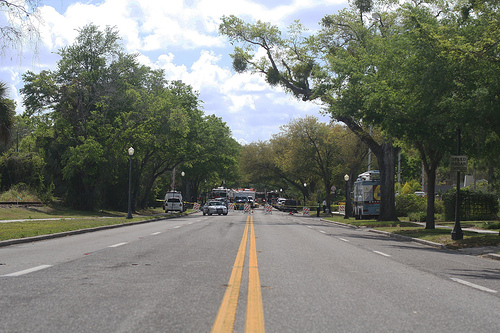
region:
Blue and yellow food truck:
[345, 167, 398, 217]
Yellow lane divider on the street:
[236, 207, 258, 329]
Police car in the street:
[195, 190, 230, 212]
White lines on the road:
[78, 212, 191, 257]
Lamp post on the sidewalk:
[121, 140, 140, 232]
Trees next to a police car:
[46, 72, 141, 201]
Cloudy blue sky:
[126, 19, 268, 111]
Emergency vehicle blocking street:
[218, 182, 287, 215]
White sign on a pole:
[452, 147, 471, 185]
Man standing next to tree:
[314, 197, 330, 214]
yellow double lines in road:
[213, 230, 269, 325]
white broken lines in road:
[330, 233, 464, 294]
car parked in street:
[195, 194, 237, 226]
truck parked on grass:
[342, 169, 392, 227]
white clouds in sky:
[189, 52, 239, 104]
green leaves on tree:
[358, 63, 420, 120]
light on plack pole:
[115, 138, 147, 219]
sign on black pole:
[443, 152, 473, 186]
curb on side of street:
[54, 223, 121, 244]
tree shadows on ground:
[347, 226, 432, 255]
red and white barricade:
[244, 203, 251, 214]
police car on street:
[205, 199, 228, 215]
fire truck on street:
[213, 185, 258, 205]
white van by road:
[166, 194, 183, 211]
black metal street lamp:
[126, 146, 136, 221]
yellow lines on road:
[217, 211, 260, 332]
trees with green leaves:
[223, 3, 490, 240]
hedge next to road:
[448, 186, 498, 223]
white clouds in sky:
[5, 1, 323, 112]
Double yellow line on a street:
[213, 235, 269, 331]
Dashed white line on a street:
[107, 235, 131, 258]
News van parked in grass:
[346, 164, 390, 223]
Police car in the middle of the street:
[201, 200, 227, 215]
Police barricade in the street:
[226, 201, 274, 215]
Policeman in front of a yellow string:
[314, 199, 322, 214]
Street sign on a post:
[448, 150, 470, 175]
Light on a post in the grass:
[123, 144, 135, 219]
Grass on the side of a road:
[13, 222, 72, 234]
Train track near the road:
[3, 192, 60, 204]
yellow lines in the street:
[218, 210, 273, 311]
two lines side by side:
[207, 204, 271, 321]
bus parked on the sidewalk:
[339, 154, 390, 221]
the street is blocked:
[232, 190, 319, 225]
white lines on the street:
[275, 202, 487, 297]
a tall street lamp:
[119, 136, 139, 221]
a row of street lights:
[245, 177, 349, 210]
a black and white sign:
[432, 142, 476, 177]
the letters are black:
[440, 140, 474, 184]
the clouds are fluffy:
[111, 4, 281, 117]